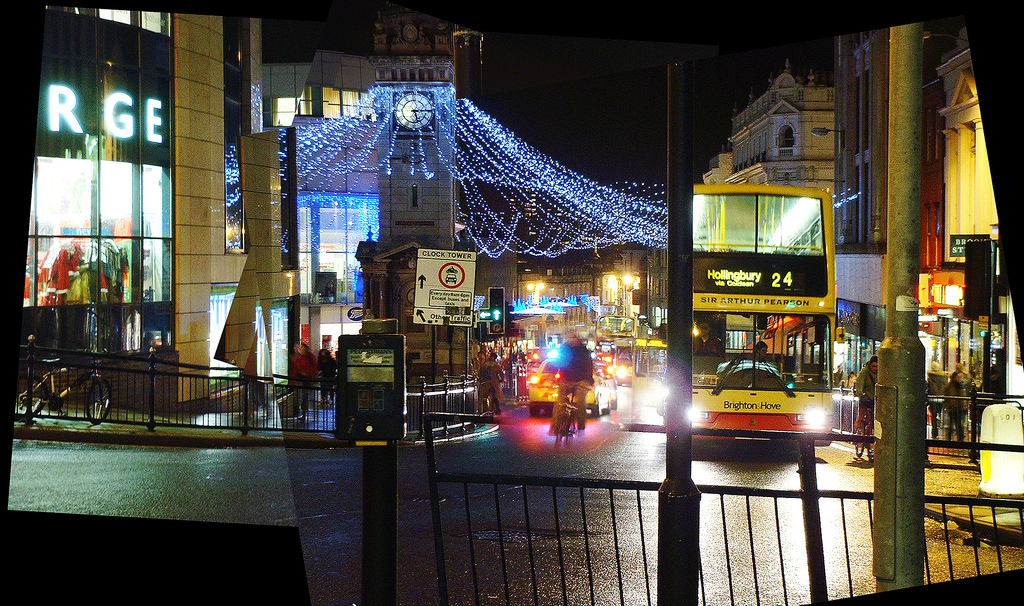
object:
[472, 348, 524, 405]
people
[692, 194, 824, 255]
clear/clean glass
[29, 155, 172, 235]
clear/clean glass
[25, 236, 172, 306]
clear/clean glass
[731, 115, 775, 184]
wall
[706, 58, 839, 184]
building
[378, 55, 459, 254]
wall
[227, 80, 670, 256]
blue lights